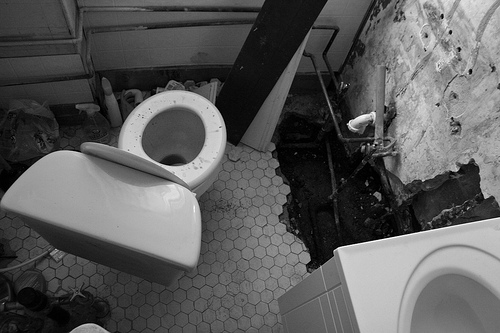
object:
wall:
[336, 0, 498, 247]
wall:
[0, 0, 378, 125]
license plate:
[83, 22, 254, 73]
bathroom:
[0, 0, 499, 332]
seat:
[116, 89, 228, 189]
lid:
[77, 140, 189, 187]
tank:
[0, 148, 206, 288]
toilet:
[0, 89, 230, 289]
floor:
[0, 126, 315, 332]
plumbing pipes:
[300, 50, 373, 144]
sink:
[275, 216, 499, 333]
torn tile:
[276, 182, 292, 197]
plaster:
[310, 25, 340, 90]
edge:
[393, 276, 429, 333]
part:
[110, 222, 135, 232]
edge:
[141, 251, 196, 273]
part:
[414, 186, 464, 210]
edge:
[356, 49, 394, 87]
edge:
[196, 202, 204, 265]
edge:
[331, 234, 405, 252]